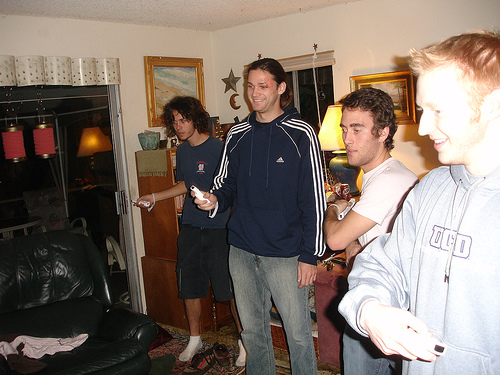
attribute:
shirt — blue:
[174, 138, 231, 230]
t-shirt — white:
[352, 157, 421, 245]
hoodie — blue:
[209, 111, 329, 268]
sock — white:
[179, 335, 203, 363]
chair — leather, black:
[1, 228, 159, 373]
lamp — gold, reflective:
[77, 127, 113, 186]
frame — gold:
[142, 54, 208, 130]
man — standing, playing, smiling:
[190, 58, 330, 374]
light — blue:
[317, 104, 360, 197]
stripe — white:
[286, 120, 329, 260]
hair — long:
[251, 58, 295, 110]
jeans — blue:
[228, 244, 320, 374]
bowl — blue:
[136, 129, 162, 150]